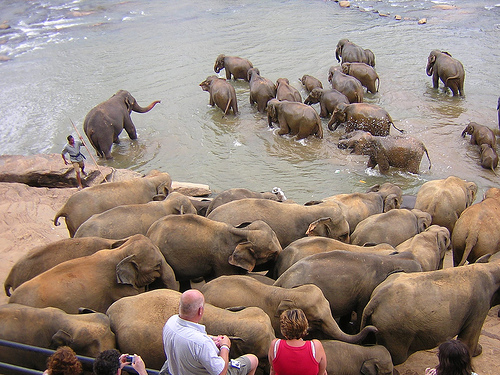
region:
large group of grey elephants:
[42, 28, 494, 341]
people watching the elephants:
[50, 291, 322, 368]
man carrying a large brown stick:
[60, 104, 112, 183]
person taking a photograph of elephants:
[95, 336, 148, 371]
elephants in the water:
[210, 26, 480, 173]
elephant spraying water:
[313, 111, 444, 179]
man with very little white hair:
[176, 281, 216, 332]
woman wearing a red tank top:
[265, 309, 331, 371]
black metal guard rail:
[14, 340, 66, 372]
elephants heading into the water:
[112, 148, 488, 310]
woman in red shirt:
[257, 308, 329, 373]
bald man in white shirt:
[143, 289, 229, 372]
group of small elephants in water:
[202, 35, 404, 156]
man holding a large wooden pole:
[62, 116, 114, 190]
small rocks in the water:
[329, 0, 440, 32]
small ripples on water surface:
[13, 17, 73, 44]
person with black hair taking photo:
[90, 342, 147, 374]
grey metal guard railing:
[5, 337, 45, 356]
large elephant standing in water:
[84, 80, 178, 159]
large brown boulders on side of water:
[6, 189, 53, 246]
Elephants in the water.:
[78, 55, 485, 216]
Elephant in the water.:
[71, 74, 187, 180]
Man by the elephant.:
[56, 105, 119, 192]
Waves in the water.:
[35, 15, 152, 59]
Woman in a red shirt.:
[283, 291, 330, 373]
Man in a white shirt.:
[153, 292, 218, 359]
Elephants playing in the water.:
[257, 92, 441, 188]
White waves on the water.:
[19, 15, 113, 79]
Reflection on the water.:
[161, 57, 241, 152]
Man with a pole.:
[60, 106, 126, 190]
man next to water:
[48, 133, 80, 192]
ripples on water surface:
[201, 122, 246, 149]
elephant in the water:
[76, 82, 156, 164]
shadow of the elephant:
[423, 95, 474, 126]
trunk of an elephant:
[137, 91, 165, 127]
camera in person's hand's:
[118, 346, 143, 368]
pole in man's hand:
[66, 105, 82, 163]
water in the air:
[354, 113, 404, 135]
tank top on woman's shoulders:
[257, 332, 325, 367]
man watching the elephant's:
[162, 285, 226, 354]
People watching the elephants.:
[152, 267, 297, 374]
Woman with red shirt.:
[258, 298, 309, 367]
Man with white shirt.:
[146, 280, 229, 373]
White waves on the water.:
[9, 7, 155, 50]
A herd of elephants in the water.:
[179, 15, 489, 212]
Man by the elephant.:
[16, 129, 169, 241]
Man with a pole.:
[66, 102, 175, 214]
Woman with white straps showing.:
[222, 296, 329, 373]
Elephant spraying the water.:
[316, 130, 491, 181]